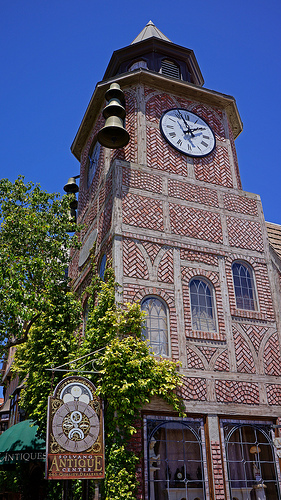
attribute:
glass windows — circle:
[143, 416, 207, 497]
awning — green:
[1, 418, 48, 467]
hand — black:
[177, 109, 194, 138]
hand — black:
[184, 127, 206, 134]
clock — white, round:
[158, 107, 214, 158]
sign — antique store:
[43, 372, 108, 483]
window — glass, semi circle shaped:
[222, 423, 280, 498]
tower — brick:
[112, 11, 244, 335]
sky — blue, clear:
[6, 18, 68, 132]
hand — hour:
[174, 125, 203, 132]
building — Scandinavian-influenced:
[104, 57, 275, 266]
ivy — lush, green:
[52, 255, 187, 495]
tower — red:
[70, 13, 245, 186]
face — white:
[170, 111, 212, 147]